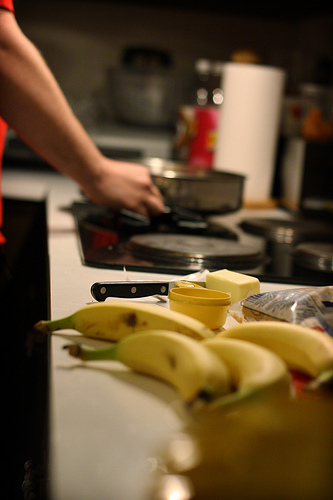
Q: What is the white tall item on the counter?
A: Paper Towel Roll.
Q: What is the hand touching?
A: A pan.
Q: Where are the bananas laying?
A: On the counter.